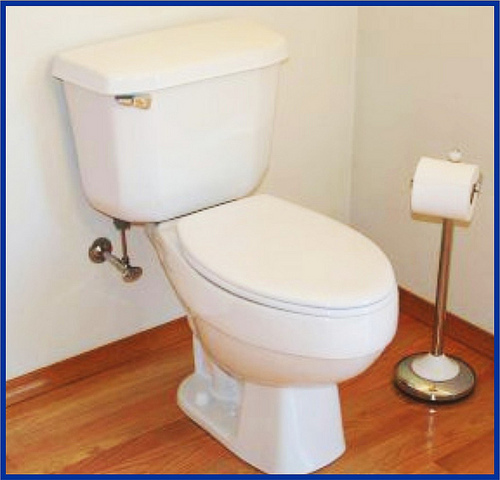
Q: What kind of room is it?
A: It is a bathroom.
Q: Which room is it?
A: It is a bathroom.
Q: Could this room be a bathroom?
A: Yes, it is a bathroom.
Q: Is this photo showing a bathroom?
A: Yes, it is showing a bathroom.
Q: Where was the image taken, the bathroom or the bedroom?
A: It was taken at the bathroom.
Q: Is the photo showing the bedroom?
A: No, the picture is showing the bathroom.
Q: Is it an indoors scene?
A: Yes, it is indoors.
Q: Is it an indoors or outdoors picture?
A: It is indoors.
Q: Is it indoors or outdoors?
A: It is indoors.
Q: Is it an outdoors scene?
A: No, it is indoors.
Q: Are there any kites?
A: No, there are no kites.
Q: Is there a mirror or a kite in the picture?
A: No, there are no kites or mirrors.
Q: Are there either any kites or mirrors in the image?
A: No, there are no kites or mirrors.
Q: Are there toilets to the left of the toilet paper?
A: Yes, there is a toilet to the left of the toilet paper.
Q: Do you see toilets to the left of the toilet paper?
A: Yes, there is a toilet to the left of the toilet paper.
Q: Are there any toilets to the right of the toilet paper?
A: No, the toilet is to the left of the toilet paper.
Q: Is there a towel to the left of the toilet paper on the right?
A: No, there is a toilet to the left of the toilet paper.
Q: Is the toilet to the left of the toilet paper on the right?
A: Yes, the toilet is to the left of the toilet paper.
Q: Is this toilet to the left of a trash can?
A: No, the toilet is to the left of the toilet paper.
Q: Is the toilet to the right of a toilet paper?
A: No, the toilet is to the left of a toilet paper.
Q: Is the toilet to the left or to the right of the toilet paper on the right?
A: The toilet is to the left of the toilet paper.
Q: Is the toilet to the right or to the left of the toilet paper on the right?
A: The toilet is to the left of the toilet paper.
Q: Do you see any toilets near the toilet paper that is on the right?
A: Yes, there is a toilet near the toilet paper.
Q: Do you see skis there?
A: No, there are no skis.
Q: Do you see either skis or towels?
A: No, there are no skis or towels.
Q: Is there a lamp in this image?
A: No, there are no lamps.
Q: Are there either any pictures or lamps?
A: No, there are no lamps or pictures.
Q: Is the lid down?
A: Yes, the lid is down.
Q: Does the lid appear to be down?
A: Yes, the lid is down.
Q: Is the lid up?
A: No, the lid is down.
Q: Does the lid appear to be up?
A: No, the lid is down.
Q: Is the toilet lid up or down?
A: The lid is down.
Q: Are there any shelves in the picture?
A: No, there are no shelves.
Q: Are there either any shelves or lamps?
A: No, there are no shelves or lamps.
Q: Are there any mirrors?
A: No, there are no mirrors.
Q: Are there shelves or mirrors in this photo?
A: No, there are no mirrors or shelves.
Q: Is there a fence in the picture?
A: No, there are no fences.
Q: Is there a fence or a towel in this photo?
A: No, there are no fences or towels.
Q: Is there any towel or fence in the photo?
A: No, there are no fences or towels.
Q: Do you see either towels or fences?
A: No, there are no fences or towels.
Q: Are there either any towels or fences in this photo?
A: No, there are no fences or towels.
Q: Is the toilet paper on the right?
A: Yes, the toilet paper is on the right of the image.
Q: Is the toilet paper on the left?
A: No, the toilet paper is on the right of the image.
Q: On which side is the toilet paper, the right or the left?
A: The toilet paper is on the right of the image.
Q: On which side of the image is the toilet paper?
A: The toilet paper is on the right of the image.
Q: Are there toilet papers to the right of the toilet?
A: Yes, there is a toilet paper to the right of the toilet.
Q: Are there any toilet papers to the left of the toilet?
A: No, the toilet paper is to the right of the toilet.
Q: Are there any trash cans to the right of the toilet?
A: No, there is a toilet paper to the right of the toilet.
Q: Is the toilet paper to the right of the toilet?
A: Yes, the toilet paper is to the right of the toilet.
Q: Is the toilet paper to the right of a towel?
A: No, the toilet paper is to the right of the toilet.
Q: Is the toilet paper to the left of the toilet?
A: No, the toilet paper is to the right of the toilet.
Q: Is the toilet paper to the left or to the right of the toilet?
A: The toilet paper is to the right of the toilet.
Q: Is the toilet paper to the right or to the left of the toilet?
A: The toilet paper is to the right of the toilet.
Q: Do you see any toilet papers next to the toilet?
A: Yes, there is a toilet paper next to the toilet.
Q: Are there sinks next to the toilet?
A: No, there is a toilet paper next to the toilet.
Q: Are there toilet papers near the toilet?
A: Yes, there is a toilet paper near the toilet.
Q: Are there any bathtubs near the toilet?
A: No, there is a toilet paper near the toilet.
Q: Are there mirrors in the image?
A: No, there are no mirrors.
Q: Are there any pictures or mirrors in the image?
A: No, there are no mirrors or pictures.